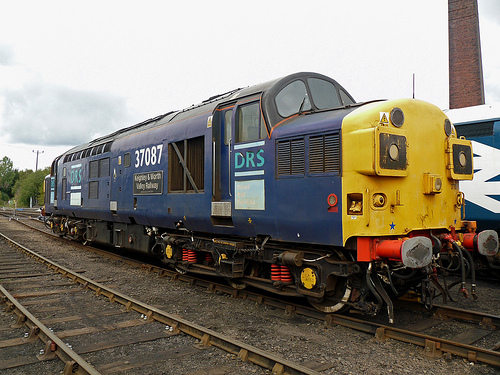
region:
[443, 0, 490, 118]
part of a tall brick column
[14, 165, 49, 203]
a large green tree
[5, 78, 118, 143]
a large white cloud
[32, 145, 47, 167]
part of a tall light pole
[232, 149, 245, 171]
a green capital letter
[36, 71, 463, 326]
a blue and yellow train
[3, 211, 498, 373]
train tracks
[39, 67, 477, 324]
blue and yellow train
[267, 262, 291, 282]
red metal springs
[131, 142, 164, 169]
white numbers on side of train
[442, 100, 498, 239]
white and blue train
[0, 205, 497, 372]
old metal train tracks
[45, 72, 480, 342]
train on train tracks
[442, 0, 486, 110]
tall brick smoke stack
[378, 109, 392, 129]
white sticker with yellow triangle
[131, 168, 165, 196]
black and white sign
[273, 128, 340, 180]
two metal grates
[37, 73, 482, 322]
blue and yellow train on tracks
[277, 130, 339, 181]
two dark metal grates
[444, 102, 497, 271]
blue and white train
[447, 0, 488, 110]
dark brown brick smoke stack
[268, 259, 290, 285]
two red metal springs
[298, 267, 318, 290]
yellow metal circle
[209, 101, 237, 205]
train door with railings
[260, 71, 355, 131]
three train windows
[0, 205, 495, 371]
old rusty metal train tracks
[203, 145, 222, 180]
a handle on the train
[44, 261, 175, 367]
a set of train tracks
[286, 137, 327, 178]
a vent on the train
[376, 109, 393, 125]
a sticker on the train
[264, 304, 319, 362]
gravel between the tracks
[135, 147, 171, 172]
numbers on the train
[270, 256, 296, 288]
springs on the train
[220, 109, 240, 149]
a door on the train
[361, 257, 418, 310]
cords on the train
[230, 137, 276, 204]
a sign on the train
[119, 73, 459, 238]
a train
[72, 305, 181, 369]
the train tracks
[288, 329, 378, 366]
small rocks on the ground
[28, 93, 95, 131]
a white cloud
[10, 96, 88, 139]
a cloud in the sky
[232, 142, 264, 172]
letters on the train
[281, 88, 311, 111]
windshield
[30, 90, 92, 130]
a cloudy sky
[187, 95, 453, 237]
a blue and yellow train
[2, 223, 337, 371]
empty railroad tracks next to train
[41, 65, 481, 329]
dark blue and yellow railroad engine car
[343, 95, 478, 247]
yellow front end of engine